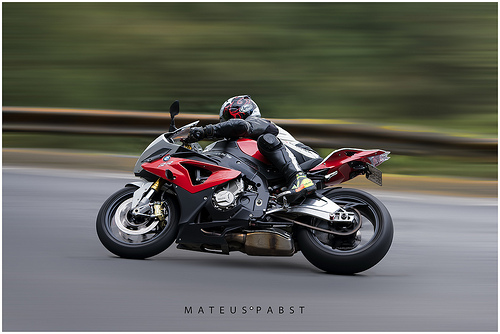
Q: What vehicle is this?
A: Motorcycle.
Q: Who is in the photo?
A: A motorcyclist.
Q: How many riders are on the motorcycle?
A: One.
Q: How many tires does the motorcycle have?
A: Two.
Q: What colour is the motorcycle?
A: Red and black.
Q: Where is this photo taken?
A: On a road.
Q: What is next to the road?
A: Trees.